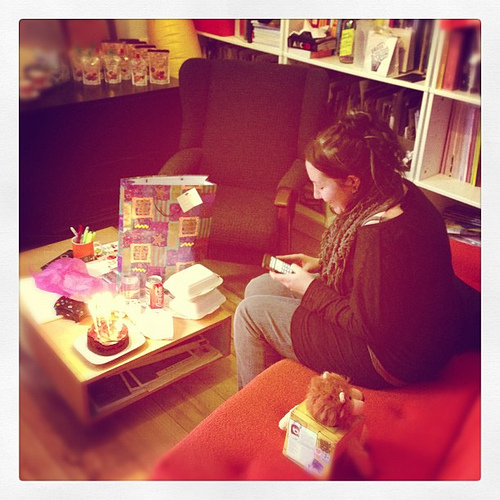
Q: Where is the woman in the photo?
A: On a sofa.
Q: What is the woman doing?
A: On phone.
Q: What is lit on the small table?
A: Cake.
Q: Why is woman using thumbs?
A: Woman is texting.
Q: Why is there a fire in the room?
A: Birthday candles.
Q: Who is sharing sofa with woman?
A: Stuffed toy.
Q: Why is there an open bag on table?
A: Contains gift.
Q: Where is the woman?
A: Living room.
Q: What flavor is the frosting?
A: Chocolate.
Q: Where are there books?
A: Shelves.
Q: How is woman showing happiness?
A: Smiling.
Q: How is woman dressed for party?
A: Casually.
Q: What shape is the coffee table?
A: Square.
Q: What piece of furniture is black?
A: A chair.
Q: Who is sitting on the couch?
A: A woman.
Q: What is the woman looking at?
A: A cell phone.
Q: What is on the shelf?
A: Books.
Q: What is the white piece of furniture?
A: A bookshelf.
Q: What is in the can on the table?
A: Soda.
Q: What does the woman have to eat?
A: Take out.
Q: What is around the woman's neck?
A: A scarf.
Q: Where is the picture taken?
A: A living room.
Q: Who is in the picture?
A: A woman.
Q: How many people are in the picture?
A: One.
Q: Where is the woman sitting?
A: On the couch.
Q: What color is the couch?
A: Red.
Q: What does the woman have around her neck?
A: A scarf.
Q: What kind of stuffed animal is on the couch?
A: A lion.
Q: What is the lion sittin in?
A: A box.